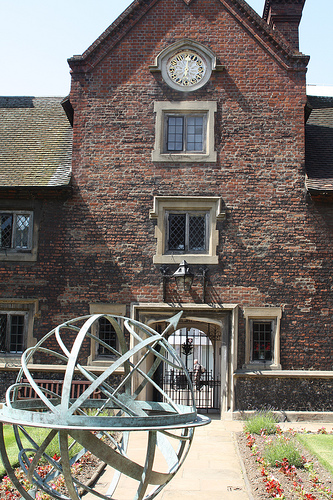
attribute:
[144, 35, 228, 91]
frame — grey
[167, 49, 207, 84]
clock — white-faced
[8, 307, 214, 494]
sculpture — spherical, metallic